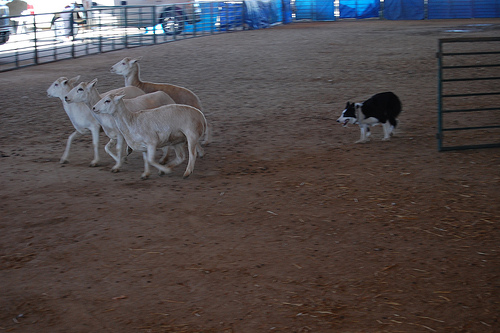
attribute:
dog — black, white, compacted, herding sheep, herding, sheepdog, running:
[336, 89, 402, 142]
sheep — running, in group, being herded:
[95, 94, 204, 178]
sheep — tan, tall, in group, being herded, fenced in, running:
[113, 56, 200, 106]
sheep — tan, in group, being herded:
[65, 78, 99, 106]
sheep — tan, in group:
[45, 75, 102, 166]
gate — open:
[437, 35, 499, 152]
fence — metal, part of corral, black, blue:
[0, 0, 499, 76]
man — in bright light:
[57, 4, 75, 36]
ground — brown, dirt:
[0, 23, 495, 331]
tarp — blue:
[183, 2, 492, 34]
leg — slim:
[59, 124, 76, 166]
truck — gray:
[78, 1, 202, 38]